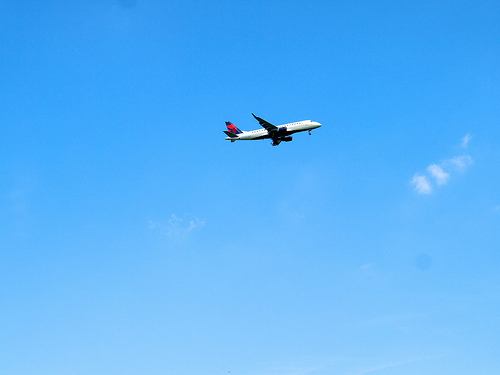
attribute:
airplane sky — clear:
[23, 9, 480, 364]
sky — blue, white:
[1, 4, 498, 364]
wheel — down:
[274, 137, 282, 145]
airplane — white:
[223, 112, 320, 146]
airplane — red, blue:
[221, 111, 323, 143]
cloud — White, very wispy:
[372, 100, 499, 229]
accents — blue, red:
[215, 111, 245, 142]